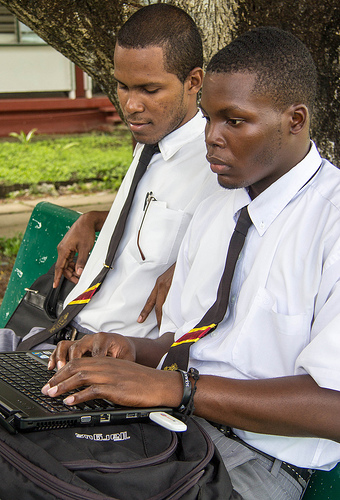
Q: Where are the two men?
A: Sitting on a bench.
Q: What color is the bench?
A: Green.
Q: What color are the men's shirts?
A: White.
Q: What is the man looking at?
A: Computer screen.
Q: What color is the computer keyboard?
A: Black.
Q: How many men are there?
A: Two.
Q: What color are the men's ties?
A: Red, Black, and Yellow.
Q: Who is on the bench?
A: Two men.